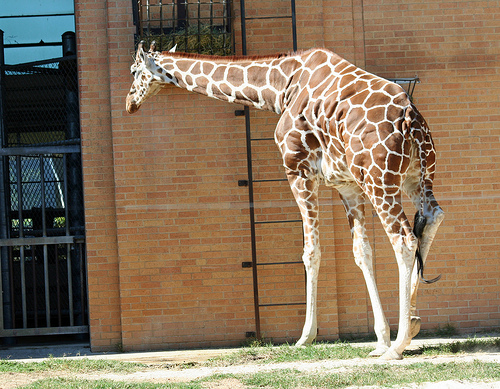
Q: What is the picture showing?
A: It is showing a pen.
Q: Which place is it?
A: It is a pen.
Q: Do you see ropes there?
A: No, there are no ropes.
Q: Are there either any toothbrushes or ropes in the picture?
A: No, there are no ropes or toothbrushes.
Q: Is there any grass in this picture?
A: Yes, there is grass.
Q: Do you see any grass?
A: Yes, there is grass.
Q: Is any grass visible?
A: Yes, there is grass.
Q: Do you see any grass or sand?
A: Yes, there is grass.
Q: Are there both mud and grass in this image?
A: No, there is grass but no mud.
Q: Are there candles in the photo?
A: No, there are no candles.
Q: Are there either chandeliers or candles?
A: No, there are no candles or chandeliers.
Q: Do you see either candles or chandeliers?
A: No, there are no candles or chandeliers.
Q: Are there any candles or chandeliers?
A: No, there are no candles or chandeliers.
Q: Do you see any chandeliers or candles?
A: No, there are no candles or chandeliers.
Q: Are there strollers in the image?
A: No, there are no strollers.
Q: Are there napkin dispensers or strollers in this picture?
A: No, there are no strollers or napkin dispensers.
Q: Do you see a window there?
A: Yes, there are windows.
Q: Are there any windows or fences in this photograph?
A: Yes, there are windows.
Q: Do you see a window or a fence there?
A: Yes, there are windows.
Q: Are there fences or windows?
A: Yes, there are windows.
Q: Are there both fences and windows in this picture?
A: Yes, there are both windows and a fence.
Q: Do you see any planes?
A: No, there are no planes.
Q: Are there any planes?
A: No, there are no planes.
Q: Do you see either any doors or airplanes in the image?
A: No, there are no airplanes or doors.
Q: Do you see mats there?
A: No, there are no mats.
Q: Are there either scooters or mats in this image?
A: No, there are no mats or scooters.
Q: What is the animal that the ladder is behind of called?
A: The animal is a giraffe.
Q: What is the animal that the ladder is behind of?
A: The animal is a giraffe.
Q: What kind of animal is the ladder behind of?
A: The ladder is behind the giraffe.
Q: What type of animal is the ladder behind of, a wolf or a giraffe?
A: The ladder is behind a giraffe.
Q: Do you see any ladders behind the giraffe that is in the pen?
A: Yes, there is a ladder behind the giraffe.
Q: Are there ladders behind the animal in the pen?
A: Yes, there is a ladder behind the giraffe.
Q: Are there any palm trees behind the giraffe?
A: No, there is a ladder behind the giraffe.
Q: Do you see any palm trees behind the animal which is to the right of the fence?
A: No, there is a ladder behind the giraffe.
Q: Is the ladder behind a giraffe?
A: Yes, the ladder is behind a giraffe.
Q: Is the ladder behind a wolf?
A: No, the ladder is behind a giraffe.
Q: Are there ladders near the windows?
A: Yes, there is a ladder near the windows.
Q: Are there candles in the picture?
A: No, there are no candles.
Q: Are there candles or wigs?
A: No, there are no candles or wigs.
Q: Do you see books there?
A: No, there are no books.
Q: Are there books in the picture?
A: No, there are no books.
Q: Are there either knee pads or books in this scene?
A: No, there are no books or knee pads.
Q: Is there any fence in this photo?
A: Yes, there is a fence.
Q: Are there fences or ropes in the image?
A: Yes, there is a fence.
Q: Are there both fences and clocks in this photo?
A: No, there is a fence but no clocks.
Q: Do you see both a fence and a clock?
A: No, there is a fence but no clocks.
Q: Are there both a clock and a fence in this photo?
A: No, there is a fence but no clocks.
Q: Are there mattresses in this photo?
A: No, there are no mattresses.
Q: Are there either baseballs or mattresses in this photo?
A: No, there are no mattresses or baseballs.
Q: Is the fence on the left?
A: Yes, the fence is on the left of the image.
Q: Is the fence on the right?
A: No, the fence is on the left of the image.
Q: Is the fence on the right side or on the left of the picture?
A: The fence is on the left of the image.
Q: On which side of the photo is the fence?
A: The fence is on the left of the image.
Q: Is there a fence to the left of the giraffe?
A: Yes, there is a fence to the left of the giraffe.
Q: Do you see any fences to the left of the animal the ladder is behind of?
A: Yes, there is a fence to the left of the giraffe.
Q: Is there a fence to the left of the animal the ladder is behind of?
A: Yes, there is a fence to the left of the giraffe.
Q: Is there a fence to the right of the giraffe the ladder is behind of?
A: No, the fence is to the left of the giraffe.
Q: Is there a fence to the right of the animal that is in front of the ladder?
A: No, the fence is to the left of the giraffe.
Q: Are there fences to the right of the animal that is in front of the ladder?
A: No, the fence is to the left of the giraffe.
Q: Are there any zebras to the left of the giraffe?
A: No, there is a fence to the left of the giraffe.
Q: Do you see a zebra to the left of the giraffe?
A: No, there is a fence to the left of the giraffe.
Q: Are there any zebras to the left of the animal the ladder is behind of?
A: No, there is a fence to the left of the giraffe.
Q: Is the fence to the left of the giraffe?
A: Yes, the fence is to the left of the giraffe.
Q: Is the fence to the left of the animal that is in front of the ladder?
A: Yes, the fence is to the left of the giraffe.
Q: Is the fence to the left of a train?
A: No, the fence is to the left of the giraffe.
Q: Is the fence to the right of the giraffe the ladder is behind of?
A: No, the fence is to the left of the giraffe.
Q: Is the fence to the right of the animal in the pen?
A: No, the fence is to the left of the giraffe.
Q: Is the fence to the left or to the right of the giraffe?
A: The fence is to the left of the giraffe.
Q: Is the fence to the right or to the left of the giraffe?
A: The fence is to the left of the giraffe.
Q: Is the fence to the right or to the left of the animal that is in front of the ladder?
A: The fence is to the left of the giraffe.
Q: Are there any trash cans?
A: No, there are no trash cans.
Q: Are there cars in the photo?
A: No, there are no cars.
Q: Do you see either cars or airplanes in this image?
A: No, there are no cars or airplanes.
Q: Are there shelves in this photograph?
A: No, there are no shelves.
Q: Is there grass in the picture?
A: Yes, there is grass.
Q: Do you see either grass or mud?
A: Yes, there is grass.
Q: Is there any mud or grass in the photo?
A: Yes, there is grass.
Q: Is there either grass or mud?
A: Yes, there is grass.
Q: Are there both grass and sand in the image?
A: No, there is grass but no sand.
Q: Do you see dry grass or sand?
A: Yes, there is dry grass.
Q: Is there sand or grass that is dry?
A: Yes, the grass is dry.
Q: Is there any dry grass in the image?
A: Yes, there is dry grass.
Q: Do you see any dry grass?
A: Yes, there is dry grass.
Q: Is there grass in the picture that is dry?
A: Yes, there is grass that is dry.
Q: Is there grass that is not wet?
A: Yes, there is dry grass.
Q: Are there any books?
A: No, there are no books.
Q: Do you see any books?
A: No, there are no books.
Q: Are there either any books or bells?
A: No, there are no books or bells.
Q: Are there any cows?
A: No, there are no cows.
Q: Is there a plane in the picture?
A: No, there are no airplanes.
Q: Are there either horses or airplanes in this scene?
A: No, there are no airplanes or horses.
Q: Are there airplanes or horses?
A: No, there are no airplanes or horses.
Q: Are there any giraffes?
A: Yes, there is a giraffe.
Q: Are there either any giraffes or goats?
A: Yes, there is a giraffe.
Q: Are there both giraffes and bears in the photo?
A: No, there is a giraffe but no bears.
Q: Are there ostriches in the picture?
A: No, there are no ostriches.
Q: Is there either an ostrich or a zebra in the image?
A: No, there are no ostriches or zebras.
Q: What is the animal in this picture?
A: The animal is a giraffe.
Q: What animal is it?
A: The animal is a giraffe.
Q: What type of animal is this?
A: This is a giraffe.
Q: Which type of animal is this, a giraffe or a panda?
A: This is a giraffe.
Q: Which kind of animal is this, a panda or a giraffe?
A: This is a giraffe.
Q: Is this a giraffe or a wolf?
A: This is a giraffe.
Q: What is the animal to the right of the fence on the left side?
A: The animal is a giraffe.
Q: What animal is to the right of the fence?
A: The animal is a giraffe.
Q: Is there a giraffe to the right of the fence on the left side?
A: Yes, there is a giraffe to the right of the fence.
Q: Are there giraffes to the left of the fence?
A: No, the giraffe is to the right of the fence.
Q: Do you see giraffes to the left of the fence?
A: No, the giraffe is to the right of the fence.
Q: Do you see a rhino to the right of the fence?
A: No, there is a giraffe to the right of the fence.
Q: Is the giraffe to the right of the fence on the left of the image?
A: Yes, the giraffe is to the right of the fence.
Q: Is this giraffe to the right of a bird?
A: No, the giraffe is to the right of the fence.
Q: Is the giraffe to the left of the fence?
A: No, the giraffe is to the right of the fence.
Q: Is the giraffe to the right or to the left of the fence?
A: The giraffe is to the right of the fence.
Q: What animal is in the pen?
A: The giraffe is in the pen.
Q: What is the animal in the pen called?
A: The animal is a giraffe.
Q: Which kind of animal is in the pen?
A: The animal is a giraffe.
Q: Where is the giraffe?
A: The giraffe is in the pen.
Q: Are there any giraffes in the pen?
A: Yes, there is a giraffe in the pen.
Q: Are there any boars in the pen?
A: No, there is a giraffe in the pen.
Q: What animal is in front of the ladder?
A: The giraffe is in front of the ladder.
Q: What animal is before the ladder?
A: The giraffe is in front of the ladder.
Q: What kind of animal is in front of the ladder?
A: The animal is a giraffe.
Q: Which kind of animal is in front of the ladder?
A: The animal is a giraffe.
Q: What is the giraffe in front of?
A: The giraffe is in front of the ladder.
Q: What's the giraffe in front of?
A: The giraffe is in front of the ladder.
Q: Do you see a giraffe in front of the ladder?
A: Yes, there is a giraffe in front of the ladder.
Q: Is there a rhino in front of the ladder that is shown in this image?
A: No, there is a giraffe in front of the ladder.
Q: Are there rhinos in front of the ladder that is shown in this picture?
A: No, there is a giraffe in front of the ladder.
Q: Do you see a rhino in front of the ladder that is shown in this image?
A: No, there is a giraffe in front of the ladder.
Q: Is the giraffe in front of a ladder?
A: Yes, the giraffe is in front of a ladder.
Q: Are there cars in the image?
A: No, there are no cars.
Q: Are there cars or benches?
A: No, there are no cars or benches.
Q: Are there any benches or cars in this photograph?
A: No, there are no cars or benches.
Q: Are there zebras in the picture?
A: No, there are no zebras.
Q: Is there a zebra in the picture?
A: No, there are no zebras.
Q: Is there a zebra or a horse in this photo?
A: No, there are no zebras or horses.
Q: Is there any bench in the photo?
A: No, there are no benches.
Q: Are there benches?
A: No, there are no benches.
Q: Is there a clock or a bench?
A: No, there are no benches or clocks.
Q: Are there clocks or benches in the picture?
A: No, there are no benches or clocks.